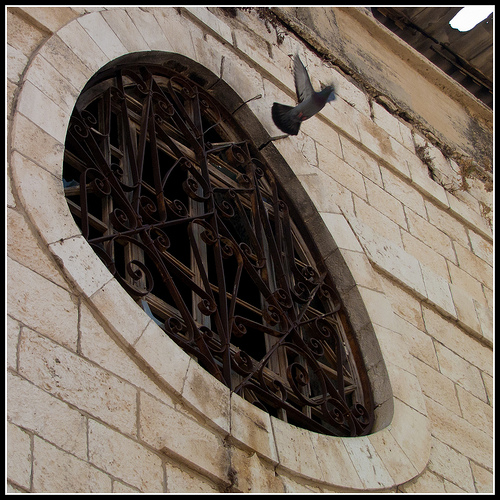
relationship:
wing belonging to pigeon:
[288, 50, 315, 102] [271, 55, 338, 134]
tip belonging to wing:
[292, 47, 300, 59] [288, 43, 316, 103]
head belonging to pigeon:
[320, 82, 334, 97] [270, 41, 382, 171]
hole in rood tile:
[442, 14, 492, 39] [420, 7, 461, 57]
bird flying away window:
[253, 50, 365, 120] [62, 25, 423, 417]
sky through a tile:
[450, 4, 492, 29] [432, 7, 484, 64]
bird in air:
[269, 41, 339, 136] [90, 26, 470, 282]